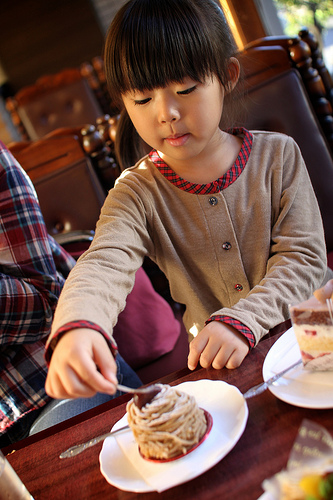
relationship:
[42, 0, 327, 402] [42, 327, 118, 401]
girl has hand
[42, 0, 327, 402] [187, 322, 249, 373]
girl has hand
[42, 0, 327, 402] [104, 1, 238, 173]
girl has hair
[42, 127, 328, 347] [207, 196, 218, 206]
shirt has button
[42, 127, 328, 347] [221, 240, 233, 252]
shirt has button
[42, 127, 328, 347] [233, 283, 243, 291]
shirt has button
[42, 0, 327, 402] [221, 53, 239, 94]
girl has ear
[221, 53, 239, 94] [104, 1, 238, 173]
ear underneath hair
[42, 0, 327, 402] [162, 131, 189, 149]
girl has lips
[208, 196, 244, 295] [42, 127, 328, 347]
buttons on front of shirt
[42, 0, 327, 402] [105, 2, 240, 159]
girl has head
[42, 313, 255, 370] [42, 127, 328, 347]
cuffs attached to shirt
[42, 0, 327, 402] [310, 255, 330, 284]
girl has elbow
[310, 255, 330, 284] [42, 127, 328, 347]
elbow inside of shirt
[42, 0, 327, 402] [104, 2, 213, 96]
girl has bangs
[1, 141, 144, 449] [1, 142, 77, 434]
person wearing shirt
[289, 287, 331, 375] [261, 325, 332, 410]
dessert on top of plate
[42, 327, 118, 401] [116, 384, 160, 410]
hand holding spoon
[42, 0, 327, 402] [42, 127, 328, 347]
girl wearing shirt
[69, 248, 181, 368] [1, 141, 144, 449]
purse behind person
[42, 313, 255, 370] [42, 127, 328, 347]
cuffs on end of shirt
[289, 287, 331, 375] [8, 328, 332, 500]
dessert on top of table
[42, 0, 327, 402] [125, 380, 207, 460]
girl swirling spaghetti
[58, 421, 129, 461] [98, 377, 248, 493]
utensil on top of plate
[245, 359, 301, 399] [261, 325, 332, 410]
utensil on top of plate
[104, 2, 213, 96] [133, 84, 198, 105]
bangs above eyes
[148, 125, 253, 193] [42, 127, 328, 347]
collar on top of shirt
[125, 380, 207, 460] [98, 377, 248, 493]
spaghetti on top of plate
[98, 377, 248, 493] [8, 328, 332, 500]
plate on top of table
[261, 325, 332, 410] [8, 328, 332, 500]
plate on top of table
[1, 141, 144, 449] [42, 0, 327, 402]
person next to girl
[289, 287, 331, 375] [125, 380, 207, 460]
dessert next to spaghetti